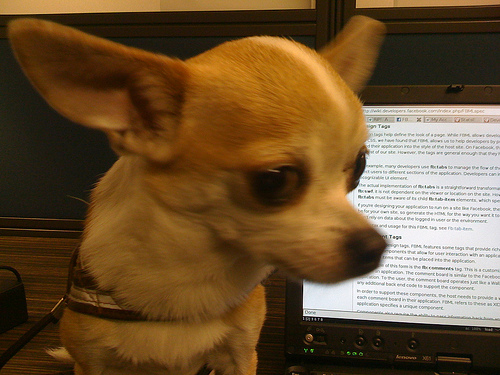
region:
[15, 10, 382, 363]
small brown dog with large ears in air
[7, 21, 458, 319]
small brown dog with large brown eyes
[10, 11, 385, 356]
small brown dog with large snout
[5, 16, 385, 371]
small brown dog sitting in front of computer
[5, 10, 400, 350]
small brown dog with brown collar on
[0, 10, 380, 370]
small brown dog sitting on wooden floor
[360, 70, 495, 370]
black laptop sitting on floor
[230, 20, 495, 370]
laptop screen with work on it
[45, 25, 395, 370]
small brown dog with black nose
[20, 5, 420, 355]
small brown dog with white streak on head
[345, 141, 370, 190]
right eye of dog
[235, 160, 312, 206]
left eye of dog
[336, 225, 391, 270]
dog nose is black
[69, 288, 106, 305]
white stripe on collar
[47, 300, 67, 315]
silver spot on leash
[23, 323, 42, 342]
black leash on dog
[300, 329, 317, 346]
power button on laptop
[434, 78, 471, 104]
camera on top laptop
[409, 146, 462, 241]
words on laptop screen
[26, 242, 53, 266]
plaid carpet on floor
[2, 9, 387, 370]
A dog in front of laptop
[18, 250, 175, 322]
A brown dog collar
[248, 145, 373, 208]
Large black dog's eyes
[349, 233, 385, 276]
Black nose of dog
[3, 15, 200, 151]
Big right ear of dog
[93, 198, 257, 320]
White far on dog's neck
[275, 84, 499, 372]
Open laptop on desk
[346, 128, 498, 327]
Writings on screen of laptop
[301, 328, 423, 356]
Buttons on a laptop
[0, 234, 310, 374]
A brown wooden surface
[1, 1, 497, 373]
a small dog sitting on table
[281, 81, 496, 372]
a monitor to a laptop computer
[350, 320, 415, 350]
three round function buttons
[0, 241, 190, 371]
a brown collar around the dog's neck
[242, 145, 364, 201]
the dog's two eyes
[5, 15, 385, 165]
a dog's two ears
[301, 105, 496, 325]
an open website page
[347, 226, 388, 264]
the dog's brown nose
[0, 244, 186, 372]
a brown dog collar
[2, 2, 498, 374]
a dog sitting on a table beside a laptop computer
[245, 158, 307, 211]
eye of hte dog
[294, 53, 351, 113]
stripe on the dog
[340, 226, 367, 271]
nose of the dog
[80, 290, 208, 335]
collar on the dog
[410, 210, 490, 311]
writing on the computer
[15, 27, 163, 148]
ear of the dog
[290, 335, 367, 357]
lights on the computer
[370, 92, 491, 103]
top of the monitor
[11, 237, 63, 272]
the desk is wood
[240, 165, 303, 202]
eye of the dog